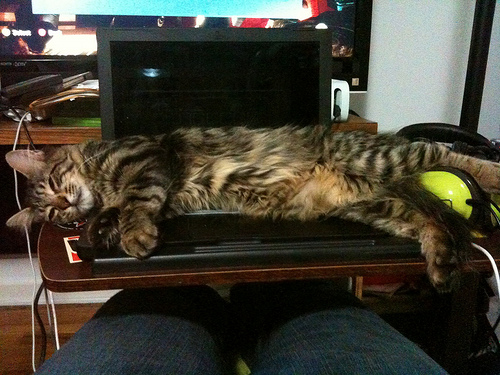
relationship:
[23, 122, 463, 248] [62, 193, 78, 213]
cat has nose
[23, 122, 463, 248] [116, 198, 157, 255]
cat with paw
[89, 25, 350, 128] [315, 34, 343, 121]
laptop has screen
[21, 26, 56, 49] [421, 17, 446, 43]
tv in back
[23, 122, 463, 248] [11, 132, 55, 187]
cat has ear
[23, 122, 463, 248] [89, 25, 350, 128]
cat on laptop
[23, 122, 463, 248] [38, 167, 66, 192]
cat has eye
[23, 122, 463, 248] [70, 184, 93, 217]
cat has mouth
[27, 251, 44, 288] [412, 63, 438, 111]
wire in wall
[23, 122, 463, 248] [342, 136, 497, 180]
cat has leg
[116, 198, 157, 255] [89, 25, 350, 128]
paw on laptop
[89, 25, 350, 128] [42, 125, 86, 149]
laptop on shelf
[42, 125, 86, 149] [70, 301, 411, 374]
shelf over jeans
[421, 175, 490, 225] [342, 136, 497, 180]
headphones under leg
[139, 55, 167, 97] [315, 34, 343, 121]
reflection on screen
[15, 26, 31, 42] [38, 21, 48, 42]
words by logos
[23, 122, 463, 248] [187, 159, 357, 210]
cat has belly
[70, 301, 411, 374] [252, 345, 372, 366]
jeans on person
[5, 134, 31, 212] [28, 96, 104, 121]
wires from phone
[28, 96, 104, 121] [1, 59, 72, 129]
phone on desk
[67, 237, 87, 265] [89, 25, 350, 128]
paper under laptop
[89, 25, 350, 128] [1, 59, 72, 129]
laptop on desk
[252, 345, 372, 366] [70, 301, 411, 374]
person in jeans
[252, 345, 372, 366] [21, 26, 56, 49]
person facing tv